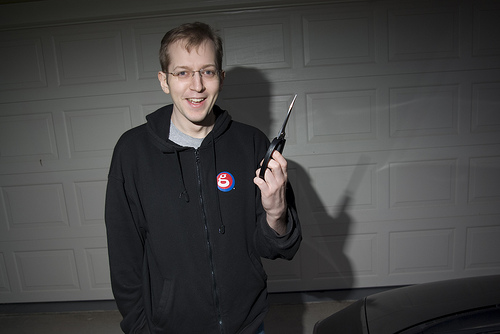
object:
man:
[103, 23, 302, 333]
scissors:
[257, 93, 299, 181]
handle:
[257, 137, 289, 180]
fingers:
[252, 176, 268, 197]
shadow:
[217, 65, 372, 333]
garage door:
[0, 1, 499, 304]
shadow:
[330, 154, 369, 221]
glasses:
[163, 69, 224, 79]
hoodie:
[101, 102, 302, 333]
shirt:
[168, 118, 205, 150]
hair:
[157, 22, 223, 86]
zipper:
[194, 148, 224, 334]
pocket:
[151, 279, 174, 327]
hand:
[251, 149, 288, 222]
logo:
[214, 171, 235, 192]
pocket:
[248, 252, 269, 288]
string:
[208, 132, 225, 235]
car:
[309, 272, 499, 334]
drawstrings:
[171, 152, 192, 200]